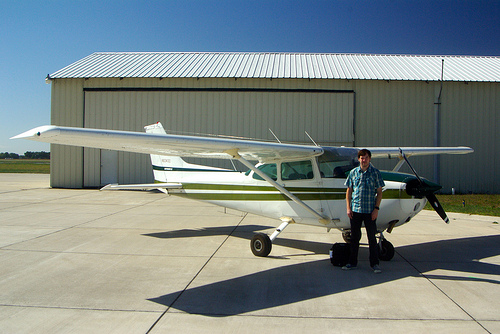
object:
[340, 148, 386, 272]
man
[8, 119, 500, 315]
plane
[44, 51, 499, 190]
hangar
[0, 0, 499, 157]
sky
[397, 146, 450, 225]
propeller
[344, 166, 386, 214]
shirt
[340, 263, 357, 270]
shoes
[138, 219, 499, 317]
shadow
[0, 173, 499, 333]
ground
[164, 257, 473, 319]
square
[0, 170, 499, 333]
tarmac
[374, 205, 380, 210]
watch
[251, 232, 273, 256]
wheel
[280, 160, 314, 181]
window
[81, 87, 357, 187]
door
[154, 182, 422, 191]
stripes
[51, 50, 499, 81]
roof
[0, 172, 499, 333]
cement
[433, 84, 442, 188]
pipe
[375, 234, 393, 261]
wheel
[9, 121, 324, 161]
wing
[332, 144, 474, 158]
wing